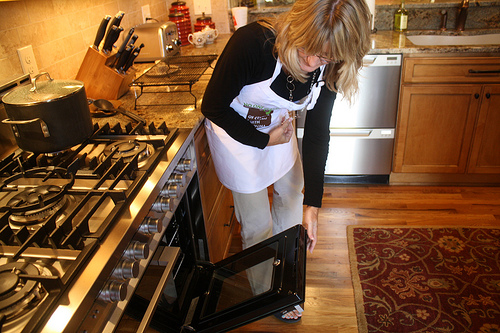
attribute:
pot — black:
[2, 72, 94, 149]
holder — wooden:
[86, 51, 123, 103]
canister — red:
[166, 5, 216, 53]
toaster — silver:
[131, 17, 179, 62]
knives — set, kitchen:
[75, 10, 145, 92]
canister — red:
[169, 14, 191, 47]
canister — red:
[166, 0, 194, 39]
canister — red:
[194, 11, 219, 43]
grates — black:
[6, 113, 188, 331]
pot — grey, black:
[4, 70, 96, 162]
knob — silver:
[121, 228, 171, 275]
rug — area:
[342, 218, 498, 327]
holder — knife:
[72, 41, 138, 105]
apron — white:
[201, 24, 328, 193]